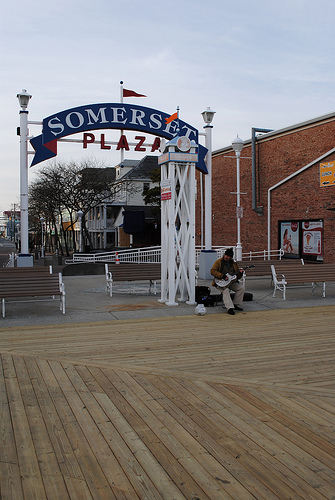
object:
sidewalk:
[0, 307, 334, 500]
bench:
[0, 265, 66, 318]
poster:
[278, 218, 324, 262]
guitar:
[214, 263, 256, 290]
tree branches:
[28, 154, 141, 256]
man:
[210, 247, 247, 315]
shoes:
[227, 304, 243, 315]